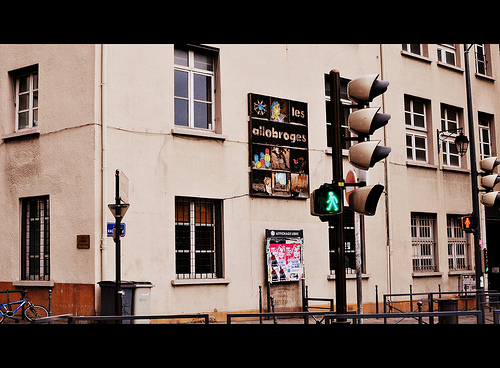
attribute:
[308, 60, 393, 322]
traffic lights —  set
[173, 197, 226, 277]
bars — black, metal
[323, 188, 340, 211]
light — green, pedestrian, walk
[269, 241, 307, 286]
poster — red, white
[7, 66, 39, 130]
windows — set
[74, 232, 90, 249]
plaque — gold, black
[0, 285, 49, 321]
bike — blue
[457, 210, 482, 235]
orange light — caution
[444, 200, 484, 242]
sign — red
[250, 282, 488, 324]
poles — black, metal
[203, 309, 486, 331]
sidewalk — city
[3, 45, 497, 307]
building — brown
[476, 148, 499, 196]
traffic lights — bordered, gold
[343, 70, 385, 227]
traffic lights — bordered, gold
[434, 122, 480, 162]
lantern — black, attached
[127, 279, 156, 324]
trash bin — black, white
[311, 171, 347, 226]
traffic sign — lighted, green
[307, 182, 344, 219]
light — street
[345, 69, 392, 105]
light — street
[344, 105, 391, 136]
light — street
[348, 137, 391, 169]
light — street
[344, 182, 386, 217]
light — street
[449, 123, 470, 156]
light — black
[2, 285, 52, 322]
bicycle —  blue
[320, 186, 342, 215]
pedestrian light — green, walk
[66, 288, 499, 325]
rails — black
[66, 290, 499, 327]
rail — black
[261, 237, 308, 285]
poster — red, white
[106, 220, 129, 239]
sign — white, blue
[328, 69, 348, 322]
pole — black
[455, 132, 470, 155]
street light — elegant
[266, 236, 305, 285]
sign — red, white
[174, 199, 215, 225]
blinds — brown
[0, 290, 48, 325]
bicycle — blue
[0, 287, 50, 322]
bicycle — blue, leaning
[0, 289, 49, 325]
bike — blue